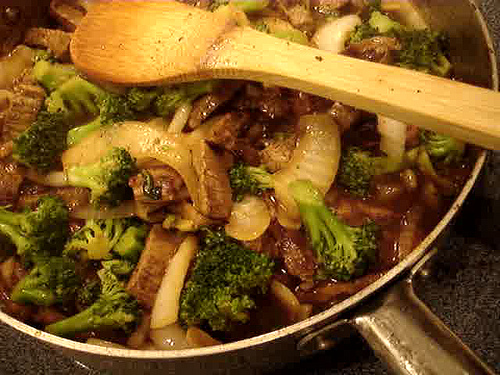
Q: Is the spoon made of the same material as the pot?
A: No, the spoon is made of wood and the pot is made of metal.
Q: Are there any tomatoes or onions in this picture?
A: Yes, there is an onion.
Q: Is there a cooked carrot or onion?
A: Yes, there is a cooked onion.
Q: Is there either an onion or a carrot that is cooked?
A: Yes, the onion is cooked.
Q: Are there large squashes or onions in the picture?
A: Yes, there is a large onion.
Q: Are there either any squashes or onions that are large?
A: Yes, the onion is large.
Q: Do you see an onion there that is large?
A: Yes, there is a large onion.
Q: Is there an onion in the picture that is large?
A: Yes, there is an onion that is large.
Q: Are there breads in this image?
A: No, there are no breads.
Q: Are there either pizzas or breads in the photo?
A: No, there are no breads or pizzas.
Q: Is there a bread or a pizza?
A: No, there are no breads or pizzas.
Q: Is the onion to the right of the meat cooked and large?
A: Yes, the onion is cooked and large.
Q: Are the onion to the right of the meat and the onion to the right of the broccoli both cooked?
A: Yes, both the onion and the onion are cooked.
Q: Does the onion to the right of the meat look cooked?
A: Yes, the onion is cooked.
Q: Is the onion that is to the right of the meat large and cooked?
A: Yes, the onion is large and cooked.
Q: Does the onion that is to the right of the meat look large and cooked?
A: Yes, the onion is large and cooked.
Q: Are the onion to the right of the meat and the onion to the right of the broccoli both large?
A: Yes, both the onion and the onion are large.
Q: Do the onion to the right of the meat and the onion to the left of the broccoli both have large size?
A: Yes, both the onion and the onion are large.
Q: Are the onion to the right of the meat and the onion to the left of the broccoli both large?
A: Yes, both the onion and the onion are large.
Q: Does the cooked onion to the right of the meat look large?
A: Yes, the onion is large.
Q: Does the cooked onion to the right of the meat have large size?
A: Yes, the onion is large.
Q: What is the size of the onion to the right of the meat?
A: The onion is large.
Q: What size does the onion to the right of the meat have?
A: The onion has large size.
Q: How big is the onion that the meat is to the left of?
A: The onion is large.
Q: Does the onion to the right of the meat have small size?
A: No, the onion is large.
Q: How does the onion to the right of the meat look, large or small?
A: The onion is large.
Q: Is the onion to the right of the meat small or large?
A: The onion is large.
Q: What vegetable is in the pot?
A: The vegetable is an onion.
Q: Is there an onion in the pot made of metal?
A: Yes, there is an onion in the pot.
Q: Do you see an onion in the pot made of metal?
A: Yes, there is an onion in the pot.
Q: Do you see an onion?
A: Yes, there is an onion.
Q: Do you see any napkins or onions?
A: Yes, there is an onion.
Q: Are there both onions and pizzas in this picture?
A: No, there is an onion but no pizzas.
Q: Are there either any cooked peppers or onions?
A: Yes, there is a cooked onion.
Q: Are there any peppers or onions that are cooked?
A: Yes, the onion is cooked.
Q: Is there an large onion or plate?
A: Yes, there is a large onion.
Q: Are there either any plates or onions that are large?
A: Yes, the onion is large.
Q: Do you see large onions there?
A: Yes, there is a large onion.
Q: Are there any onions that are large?
A: Yes, there is an onion that is large.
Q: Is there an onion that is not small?
A: Yes, there is a large onion.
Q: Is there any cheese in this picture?
A: No, there is no cheese.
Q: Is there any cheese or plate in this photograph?
A: No, there are no cheese or plates.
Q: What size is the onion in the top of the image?
A: The onion is large.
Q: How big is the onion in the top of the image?
A: The onion is large.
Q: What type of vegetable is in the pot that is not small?
A: The vegetable is an onion.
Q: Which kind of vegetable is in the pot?
A: The vegetable is an onion.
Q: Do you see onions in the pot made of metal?
A: Yes, there is an onion in the pot.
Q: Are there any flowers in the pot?
A: No, there is an onion in the pot.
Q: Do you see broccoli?
A: Yes, there is broccoli.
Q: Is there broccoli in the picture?
A: Yes, there is broccoli.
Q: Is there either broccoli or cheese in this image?
A: Yes, there is broccoli.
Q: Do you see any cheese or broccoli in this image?
A: Yes, there is broccoli.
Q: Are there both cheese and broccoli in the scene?
A: No, there is broccoli but no cheese.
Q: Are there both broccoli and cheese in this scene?
A: No, there is broccoli but no cheese.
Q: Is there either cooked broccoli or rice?
A: Yes, there is cooked broccoli.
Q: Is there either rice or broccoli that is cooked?
A: Yes, the broccoli is cooked.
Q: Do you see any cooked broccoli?
A: Yes, there is cooked broccoli.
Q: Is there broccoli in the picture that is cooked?
A: Yes, there is broccoli that is cooked.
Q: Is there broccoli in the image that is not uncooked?
A: Yes, there is cooked broccoli.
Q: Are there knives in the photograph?
A: No, there are no knives.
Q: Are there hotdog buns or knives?
A: No, there are no knives or hotdog buns.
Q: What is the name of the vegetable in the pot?
A: The vegetable is broccoli.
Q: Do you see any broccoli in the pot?
A: Yes, there is broccoli in the pot.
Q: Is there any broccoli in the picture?
A: Yes, there is broccoli.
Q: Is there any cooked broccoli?
A: Yes, there is cooked broccoli.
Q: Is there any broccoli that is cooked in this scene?
A: Yes, there is cooked broccoli.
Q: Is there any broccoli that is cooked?
A: Yes, there is broccoli that is cooked.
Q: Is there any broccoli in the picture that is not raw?
A: Yes, there is cooked broccoli.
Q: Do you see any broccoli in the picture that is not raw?
A: Yes, there is cooked broccoli.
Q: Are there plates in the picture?
A: No, there are no plates.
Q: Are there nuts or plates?
A: No, there are no plates or nuts.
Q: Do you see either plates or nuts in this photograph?
A: No, there are no plates or nuts.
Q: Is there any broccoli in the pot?
A: Yes, there is broccoli in the pot.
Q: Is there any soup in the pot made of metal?
A: No, there is broccoli in the pot.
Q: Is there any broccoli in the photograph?
A: Yes, there is broccoli.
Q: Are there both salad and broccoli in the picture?
A: No, there is broccoli but no salad.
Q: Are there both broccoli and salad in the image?
A: No, there is broccoli but no salad.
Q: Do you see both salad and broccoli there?
A: No, there is broccoli but no salad.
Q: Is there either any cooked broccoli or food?
A: Yes, there is cooked broccoli.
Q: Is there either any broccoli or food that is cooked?
A: Yes, the broccoli is cooked.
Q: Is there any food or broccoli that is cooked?
A: Yes, the broccoli is cooked.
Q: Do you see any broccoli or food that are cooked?
A: Yes, the broccoli is cooked.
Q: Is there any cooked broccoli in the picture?
A: Yes, there is cooked broccoli.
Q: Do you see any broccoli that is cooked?
A: Yes, there is broccoli that is cooked.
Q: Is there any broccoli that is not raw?
A: Yes, there is cooked broccoli.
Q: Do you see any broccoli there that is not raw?
A: Yes, there is cooked broccoli.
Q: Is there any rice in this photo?
A: No, there is no rice.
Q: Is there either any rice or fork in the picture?
A: No, there are no rice or forks.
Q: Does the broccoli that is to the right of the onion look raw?
A: No, the broccoli is cooked.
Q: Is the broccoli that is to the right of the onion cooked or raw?
A: The broccoli is cooked.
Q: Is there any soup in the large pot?
A: No, there is broccoli in the pot.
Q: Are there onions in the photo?
A: Yes, there is an onion.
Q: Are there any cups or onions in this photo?
A: Yes, there is an onion.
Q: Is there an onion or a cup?
A: Yes, there is an onion.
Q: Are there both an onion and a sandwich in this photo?
A: No, there is an onion but no sandwiches.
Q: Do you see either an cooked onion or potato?
A: Yes, there is a cooked onion.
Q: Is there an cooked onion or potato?
A: Yes, there is a cooked onion.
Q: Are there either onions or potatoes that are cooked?
A: Yes, the onion is cooked.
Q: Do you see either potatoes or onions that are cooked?
A: Yes, the onion is cooked.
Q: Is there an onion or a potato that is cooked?
A: Yes, the onion is cooked.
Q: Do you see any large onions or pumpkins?
A: Yes, there is a large onion.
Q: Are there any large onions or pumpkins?
A: Yes, there is a large onion.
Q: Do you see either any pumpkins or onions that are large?
A: Yes, the onion is large.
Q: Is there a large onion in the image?
A: Yes, there is a large onion.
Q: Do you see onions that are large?
A: Yes, there is an onion that is large.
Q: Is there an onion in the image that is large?
A: Yes, there is an onion that is large.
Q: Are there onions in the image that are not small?
A: Yes, there is a large onion.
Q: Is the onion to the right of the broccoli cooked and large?
A: Yes, the onion is cooked and large.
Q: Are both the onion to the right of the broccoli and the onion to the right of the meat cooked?
A: Yes, both the onion and the onion are cooked.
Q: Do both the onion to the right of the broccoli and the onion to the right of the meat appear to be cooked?
A: Yes, both the onion and the onion are cooked.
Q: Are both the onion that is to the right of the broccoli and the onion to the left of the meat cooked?
A: Yes, both the onion and the onion are cooked.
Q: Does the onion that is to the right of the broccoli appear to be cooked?
A: Yes, the onion is cooked.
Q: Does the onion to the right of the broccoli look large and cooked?
A: Yes, the onion is large and cooked.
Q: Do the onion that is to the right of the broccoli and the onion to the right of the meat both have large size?
A: Yes, both the onion and the onion are large.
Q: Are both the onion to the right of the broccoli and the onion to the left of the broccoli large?
A: Yes, both the onion and the onion are large.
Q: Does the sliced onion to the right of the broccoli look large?
A: Yes, the onion is large.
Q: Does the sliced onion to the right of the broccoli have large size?
A: Yes, the onion is large.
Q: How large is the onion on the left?
A: The onion is large.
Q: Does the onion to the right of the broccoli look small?
A: No, the onion is large.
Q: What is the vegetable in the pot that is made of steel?
A: The vegetable is an onion.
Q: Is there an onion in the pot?
A: Yes, there is an onion in the pot.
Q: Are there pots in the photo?
A: Yes, there is a pot.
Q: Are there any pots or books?
A: Yes, there is a pot.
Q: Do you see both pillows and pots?
A: No, there is a pot but no pillows.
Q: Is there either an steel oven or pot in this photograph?
A: Yes, there is a steel pot.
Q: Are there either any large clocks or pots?
A: Yes, there is a large pot.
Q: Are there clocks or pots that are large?
A: Yes, the pot is large.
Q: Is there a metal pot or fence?
A: Yes, there is a metal pot.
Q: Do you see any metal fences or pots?
A: Yes, there is a metal pot.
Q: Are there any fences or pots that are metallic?
A: Yes, the pot is metallic.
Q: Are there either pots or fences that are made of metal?
A: Yes, the pot is made of metal.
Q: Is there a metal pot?
A: Yes, there is a pot that is made of metal.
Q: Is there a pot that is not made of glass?
A: Yes, there is a pot that is made of metal.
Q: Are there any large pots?
A: Yes, there is a large pot.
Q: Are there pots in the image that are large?
A: Yes, there is a pot that is large.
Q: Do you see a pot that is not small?
A: Yes, there is a large pot.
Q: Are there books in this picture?
A: No, there are no books.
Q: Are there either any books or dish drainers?
A: No, there are no books or dish drainers.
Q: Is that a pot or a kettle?
A: That is a pot.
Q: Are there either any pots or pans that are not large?
A: No, there is a pot but it is large.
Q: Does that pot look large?
A: Yes, the pot is large.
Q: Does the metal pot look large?
A: Yes, the pot is large.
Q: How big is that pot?
A: The pot is large.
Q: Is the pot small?
A: No, the pot is large.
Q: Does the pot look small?
A: No, the pot is large.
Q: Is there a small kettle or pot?
A: No, there is a pot but it is large.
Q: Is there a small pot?
A: No, there is a pot but it is large.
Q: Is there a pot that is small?
A: No, there is a pot but it is large.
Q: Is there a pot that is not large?
A: No, there is a pot but it is large.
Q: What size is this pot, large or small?
A: The pot is large.